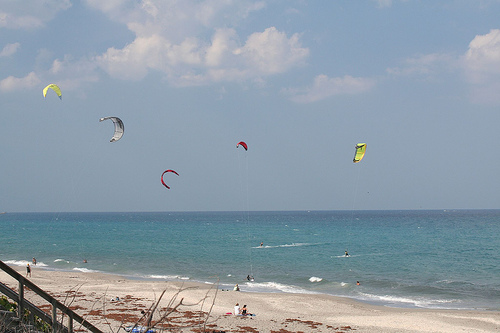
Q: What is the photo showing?
A: It is showing an ocean.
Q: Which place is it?
A: It is an ocean.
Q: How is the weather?
A: It is cloudy.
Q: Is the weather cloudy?
A: Yes, it is cloudy.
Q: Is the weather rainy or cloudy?
A: It is cloudy.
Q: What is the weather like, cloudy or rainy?
A: It is cloudy.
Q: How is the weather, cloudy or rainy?
A: It is cloudy.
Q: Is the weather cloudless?
A: No, it is cloudy.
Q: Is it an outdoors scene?
A: Yes, it is outdoors.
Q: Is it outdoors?
A: Yes, it is outdoors.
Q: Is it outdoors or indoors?
A: It is outdoors.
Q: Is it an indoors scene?
A: No, it is outdoors.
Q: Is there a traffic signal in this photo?
A: No, there are no traffic lights.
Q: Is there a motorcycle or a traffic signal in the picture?
A: No, there are no traffic lights or motorcycles.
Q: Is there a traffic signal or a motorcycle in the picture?
A: No, there are no traffic lights or motorcycles.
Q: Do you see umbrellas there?
A: No, there are no umbrellas.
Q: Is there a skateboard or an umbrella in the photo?
A: No, there are no umbrellas or skateboards.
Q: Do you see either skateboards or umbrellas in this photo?
A: No, there are no umbrellas or skateboards.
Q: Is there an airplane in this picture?
A: No, there are no airplanes.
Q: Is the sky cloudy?
A: Yes, the sky is cloudy.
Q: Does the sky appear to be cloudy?
A: Yes, the sky is cloudy.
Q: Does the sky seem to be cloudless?
A: No, the sky is cloudy.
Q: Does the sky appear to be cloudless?
A: No, the sky is cloudy.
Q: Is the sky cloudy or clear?
A: The sky is cloudy.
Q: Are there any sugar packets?
A: No, there are no sugar packets.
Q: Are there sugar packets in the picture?
A: No, there are no sugar packets.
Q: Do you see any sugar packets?
A: No, there are no sugar packets.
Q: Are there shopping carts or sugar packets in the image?
A: No, there are no sugar packets or shopping carts.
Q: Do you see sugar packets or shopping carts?
A: No, there are no sugar packets or shopping carts.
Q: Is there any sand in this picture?
A: Yes, there is sand.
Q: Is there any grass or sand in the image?
A: Yes, there is sand.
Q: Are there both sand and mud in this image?
A: No, there is sand but no mud.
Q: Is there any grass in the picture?
A: No, there is no grass.